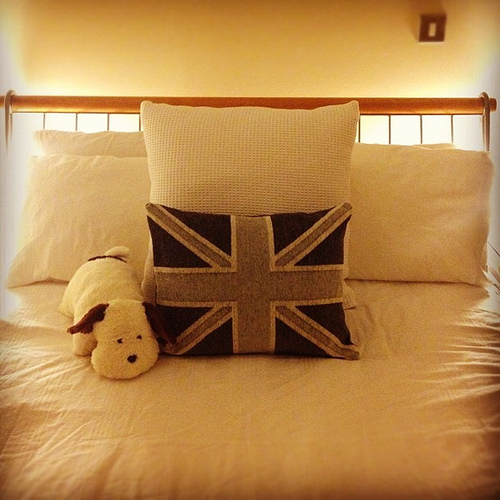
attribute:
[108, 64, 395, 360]
pillow — white, accent, small, leaning, grey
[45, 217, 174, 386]
dog — white, stuffed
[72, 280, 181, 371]
head — brown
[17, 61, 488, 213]
headboard — brown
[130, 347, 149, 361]
nose — black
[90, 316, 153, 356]
eye — black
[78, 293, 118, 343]
ear — brown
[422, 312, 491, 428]
sheet — wrinkle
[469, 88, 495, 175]
rod — wooden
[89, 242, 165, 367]
animal — stuffed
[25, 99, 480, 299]
comforter — white